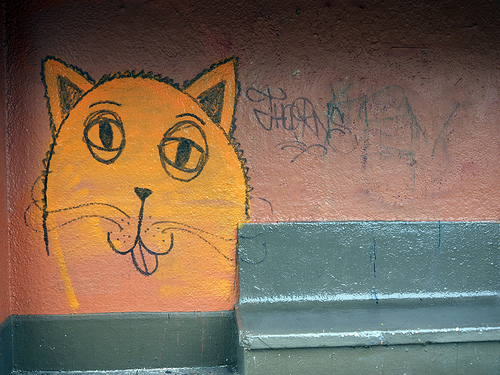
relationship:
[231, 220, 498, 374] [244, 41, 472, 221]
bench against wall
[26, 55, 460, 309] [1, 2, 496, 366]
graffiti on wall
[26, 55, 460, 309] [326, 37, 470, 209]
graffiti on wall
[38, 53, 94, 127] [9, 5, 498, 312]
ear painted on wall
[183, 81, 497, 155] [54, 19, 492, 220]
graffiti on wall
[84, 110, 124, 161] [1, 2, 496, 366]
eye on wall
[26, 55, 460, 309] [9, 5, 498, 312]
graffiti on wall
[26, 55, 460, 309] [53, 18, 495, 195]
graffiti on wall